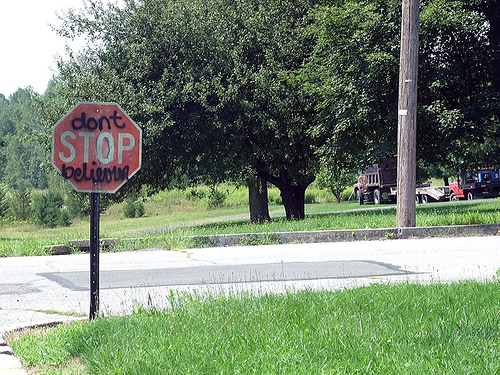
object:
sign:
[50, 102, 143, 194]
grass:
[6, 269, 499, 375]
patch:
[36, 258, 428, 293]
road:
[0, 235, 499, 323]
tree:
[48, 0, 499, 221]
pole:
[394, 0, 421, 228]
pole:
[87, 194, 100, 317]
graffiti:
[60, 111, 132, 183]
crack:
[0, 298, 87, 322]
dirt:
[53, 353, 91, 375]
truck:
[353, 161, 396, 206]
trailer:
[416, 184, 450, 203]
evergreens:
[0, 180, 167, 240]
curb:
[66, 217, 500, 257]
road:
[110, 199, 497, 235]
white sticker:
[396, 110, 405, 116]